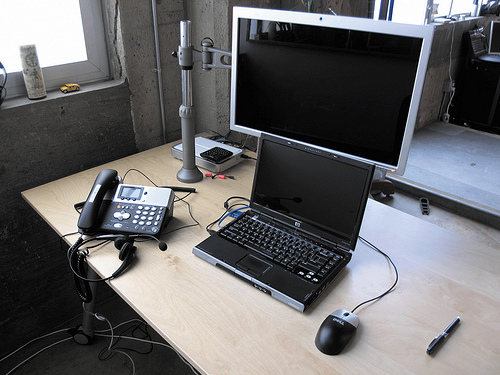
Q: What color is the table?
A: Brown.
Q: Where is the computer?
A: On the table.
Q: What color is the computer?
A: Black.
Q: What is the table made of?
A: Wood.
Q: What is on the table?
A: The computer.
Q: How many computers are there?
A: One.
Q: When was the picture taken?
A: Daytime.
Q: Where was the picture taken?
A: In an office.